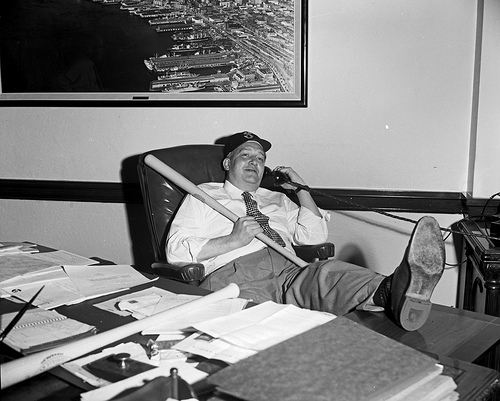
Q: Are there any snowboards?
A: No, there are no snowboards.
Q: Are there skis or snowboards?
A: No, there are no snowboards or skis.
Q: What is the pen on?
A: The pen is on the desk.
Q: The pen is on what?
A: The pen is on the desk.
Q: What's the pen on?
A: The pen is on the desk.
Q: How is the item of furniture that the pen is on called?
A: The piece of furniture is a desk.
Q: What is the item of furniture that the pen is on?
A: The piece of furniture is a desk.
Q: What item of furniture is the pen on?
A: The pen is on the desk.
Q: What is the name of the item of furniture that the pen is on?
A: The piece of furniture is a desk.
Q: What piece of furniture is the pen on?
A: The pen is on the desk.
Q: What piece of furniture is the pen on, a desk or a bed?
A: The pen is on a desk.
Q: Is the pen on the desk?
A: Yes, the pen is on the desk.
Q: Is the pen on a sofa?
A: No, the pen is on the desk.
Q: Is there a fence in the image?
A: No, there are no fences.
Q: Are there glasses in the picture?
A: No, there are no glasses.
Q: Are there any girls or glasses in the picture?
A: No, there are no glasses or girls.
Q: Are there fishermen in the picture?
A: No, there are no fishermen.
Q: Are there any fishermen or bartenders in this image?
A: No, there are no fishermen or bartenders.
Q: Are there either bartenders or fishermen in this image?
A: No, there are no fishermen or bartenders.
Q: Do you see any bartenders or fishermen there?
A: No, there are no fishermen or bartenders.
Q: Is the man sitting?
A: Yes, the man is sitting.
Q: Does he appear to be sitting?
A: Yes, the man is sitting.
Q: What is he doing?
A: The man is sitting.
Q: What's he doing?
A: The man is sitting.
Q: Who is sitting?
A: The man is sitting.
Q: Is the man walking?
A: No, the man is sitting.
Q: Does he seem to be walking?
A: No, the man is sitting.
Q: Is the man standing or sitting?
A: The man is sitting.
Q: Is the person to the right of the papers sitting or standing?
A: The man is sitting.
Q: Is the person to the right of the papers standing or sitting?
A: The man is sitting.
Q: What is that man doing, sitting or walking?
A: The man is sitting.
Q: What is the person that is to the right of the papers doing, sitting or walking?
A: The man is sitting.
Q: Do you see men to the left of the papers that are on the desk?
A: No, the man is to the right of the papers.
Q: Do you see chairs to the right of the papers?
A: No, there is a man to the right of the papers.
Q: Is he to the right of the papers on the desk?
A: Yes, the man is to the right of the papers.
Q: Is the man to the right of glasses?
A: No, the man is to the right of the papers.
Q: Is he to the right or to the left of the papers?
A: The man is to the right of the papers.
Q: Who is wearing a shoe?
A: The man is wearing a shoe.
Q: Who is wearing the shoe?
A: The man is wearing a shoe.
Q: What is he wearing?
A: The man is wearing a shoe.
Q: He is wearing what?
A: The man is wearing a shoe.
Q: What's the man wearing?
A: The man is wearing a shoe.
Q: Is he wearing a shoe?
A: Yes, the man is wearing a shoe.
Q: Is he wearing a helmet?
A: No, the man is wearing a shoe.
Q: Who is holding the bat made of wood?
A: The man is holding the bat.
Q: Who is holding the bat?
A: The man is holding the bat.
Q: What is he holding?
A: The man is holding the bat.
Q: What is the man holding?
A: The man is holding the bat.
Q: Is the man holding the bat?
A: Yes, the man is holding the bat.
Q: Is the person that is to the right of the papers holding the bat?
A: Yes, the man is holding the bat.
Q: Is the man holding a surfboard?
A: No, the man is holding the bat.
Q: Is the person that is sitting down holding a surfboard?
A: No, the man is holding the bat.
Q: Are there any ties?
A: Yes, there is a tie.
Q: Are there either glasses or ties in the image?
A: Yes, there is a tie.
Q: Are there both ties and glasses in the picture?
A: No, there is a tie but no glasses.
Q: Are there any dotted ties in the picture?
A: Yes, there is a dotted tie.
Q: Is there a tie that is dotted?
A: Yes, there is a tie that is dotted.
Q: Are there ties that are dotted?
A: Yes, there is a tie that is dotted.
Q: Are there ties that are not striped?
A: Yes, there is a dotted tie.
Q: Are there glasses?
A: No, there are no glasses.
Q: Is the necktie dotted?
A: Yes, the necktie is dotted.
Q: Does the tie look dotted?
A: Yes, the tie is dotted.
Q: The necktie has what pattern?
A: The necktie is dotted.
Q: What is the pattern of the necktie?
A: The necktie is dotted.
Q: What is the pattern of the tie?
A: The necktie is dotted.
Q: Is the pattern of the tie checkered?
A: No, the tie is dotted.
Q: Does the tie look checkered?
A: No, the tie is dotted.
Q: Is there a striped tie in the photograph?
A: No, there is a tie but it is dotted.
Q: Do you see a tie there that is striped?
A: No, there is a tie but it is dotted.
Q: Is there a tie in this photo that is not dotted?
A: No, there is a tie but it is dotted.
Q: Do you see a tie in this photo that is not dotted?
A: No, there is a tie but it is dotted.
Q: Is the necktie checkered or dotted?
A: The necktie is dotted.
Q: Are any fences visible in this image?
A: No, there are no fences.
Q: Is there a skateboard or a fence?
A: No, there are no fences or skateboards.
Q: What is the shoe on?
A: The shoe is on the desk.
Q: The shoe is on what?
A: The shoe is on the desk.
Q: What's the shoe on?
A: The shoe is on the desk.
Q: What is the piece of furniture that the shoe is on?
A: The piece of furniture is a desk.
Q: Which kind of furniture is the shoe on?
A: The shoe is on the desk.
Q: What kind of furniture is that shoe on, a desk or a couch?
A: The shoe is on a desk.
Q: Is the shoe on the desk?
A: Yes, the shoe is on the desk.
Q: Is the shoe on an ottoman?
A: No, the shoe is on the desk.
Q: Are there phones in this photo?
A: Yes, there is a phone.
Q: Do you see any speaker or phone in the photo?
A: Yes, there is a phone.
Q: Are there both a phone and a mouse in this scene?
A: No, there is a phone but no computer mice.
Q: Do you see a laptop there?
A: No, there are no laptops.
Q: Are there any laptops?
A: No, there are no laptops.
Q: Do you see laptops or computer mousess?
A: No, there are no laptops or computer mousess.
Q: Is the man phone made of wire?
A: Yes, the phone is made of wire.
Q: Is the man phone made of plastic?
A: No, the phone is made of wire.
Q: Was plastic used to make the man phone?
A: No, the phone is made of wire.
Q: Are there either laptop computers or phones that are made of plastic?
A: No, there is a phone but it is made of wire.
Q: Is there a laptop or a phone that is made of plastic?
A: No, there is a phone but it is made of wire.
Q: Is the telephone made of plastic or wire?
A: The telephone is made of wire.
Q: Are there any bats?
A: Yes, there is a bat.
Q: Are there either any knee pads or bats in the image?
A: Yes, there is a bat.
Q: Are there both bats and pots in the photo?
A: No, there is a bat but no pots.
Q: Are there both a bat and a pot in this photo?
A: No, there is a bat but no pots.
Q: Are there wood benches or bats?
A: Yes, there is a wood bat.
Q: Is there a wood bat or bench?
A: Yes, there is a wood bat.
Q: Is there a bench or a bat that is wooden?
A: Yes, the bat is wooden.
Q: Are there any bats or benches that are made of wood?
A: Yes, the bat is made of wood.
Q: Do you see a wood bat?
A: Yes, there is a wood bat.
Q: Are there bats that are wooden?
A: Yes, there is a bat that is wooden.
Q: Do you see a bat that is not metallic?
A: Yes, there is a wooden bat.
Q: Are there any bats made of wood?
A: Yes, there is a bat that is made of wood.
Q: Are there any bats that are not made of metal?
A: Yes, there is a bat that is made of wood.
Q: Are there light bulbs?
A: No, there are no light bulbs.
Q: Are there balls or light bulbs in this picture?
A: No, there are no light bulbs or balls.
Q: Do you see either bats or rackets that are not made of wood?
A: No, there is a bat but it is made of wood.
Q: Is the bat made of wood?
A: Yes, the bat is made of wood.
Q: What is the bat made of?
A: The bat is made of wood.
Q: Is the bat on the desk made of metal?
A: No, the bat is made of wood.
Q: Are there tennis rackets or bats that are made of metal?
A: No, there is a bat but it is made of wood.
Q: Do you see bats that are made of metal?
A: No, there is a bat but it is made of wood.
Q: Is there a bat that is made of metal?
A: No, there is a bat but it is made of wood.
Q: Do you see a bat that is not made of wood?
A: No, there is a bat but it is made of wood.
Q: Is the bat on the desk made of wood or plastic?
A: The bat is made of wood.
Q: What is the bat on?
A: The bat is on the desk.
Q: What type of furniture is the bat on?
A: The bat is on the desk.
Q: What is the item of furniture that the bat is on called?
A: The piece of furniture is a desk.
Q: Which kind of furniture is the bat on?
A: The bat is on the desk.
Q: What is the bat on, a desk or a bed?
A: The bat is on a desk.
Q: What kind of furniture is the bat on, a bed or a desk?
A: The bat is on a desk.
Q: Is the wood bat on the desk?
A: Yes, the bat is on the desk.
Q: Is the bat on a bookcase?
A: No, the bat is on the desk.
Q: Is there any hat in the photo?
A: Yes, there is a hat.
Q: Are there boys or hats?
A: Yes, there is a hat.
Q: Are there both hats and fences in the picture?
A: No, there is a hat but no fences.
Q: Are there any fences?
A: No, there are no fences.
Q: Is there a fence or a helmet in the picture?
A: No, there are no fences or helmets.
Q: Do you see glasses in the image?
A: No, there are no glasses.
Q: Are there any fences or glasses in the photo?
A: No, there are no glasses or fences.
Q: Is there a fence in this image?
A: No, there are no fences.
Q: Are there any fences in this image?
A: No, there are no fences.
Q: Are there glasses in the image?
A: No, there are no glasses.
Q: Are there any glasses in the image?
A: No, there are no glasses.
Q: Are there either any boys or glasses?
A: No, there are no glasses or boys.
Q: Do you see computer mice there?
A: No, there are no computer mice.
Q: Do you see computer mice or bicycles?
A: No, there are no computer mice or bicycles.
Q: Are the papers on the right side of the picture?
A: No, the papers are on the left of the image.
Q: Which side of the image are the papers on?
A: The papers are on the left of the image.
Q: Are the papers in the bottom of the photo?
A: Yes, the papers are in the bottom of the image.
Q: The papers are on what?
A: The papers are on the desk.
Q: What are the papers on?
A: The papers are on the desk.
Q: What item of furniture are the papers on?
A: The papers are on the desk.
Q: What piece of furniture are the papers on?
A: The papers are on the desk.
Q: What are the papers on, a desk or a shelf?
A: The papers are on a desk.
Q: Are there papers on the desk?
A: Yes, there are papers on the desk.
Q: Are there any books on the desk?
A: No, there are papers on the desk.